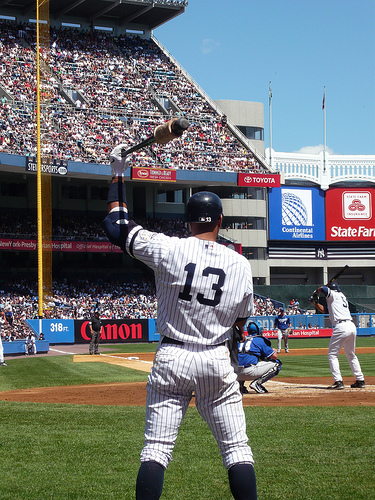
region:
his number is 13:
[169, 247, 226, 312]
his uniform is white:
[146, 245, 241, 390]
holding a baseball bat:
[100, 112, 187, 210]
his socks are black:
[114, 465, 253, 496]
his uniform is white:
[325, 288, 349, 359]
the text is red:
[61, 317, 147, 358]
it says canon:
[80, 319, 146, 344]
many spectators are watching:
[8, 272, 123, 358]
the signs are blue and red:
[270, 180, 368, 243]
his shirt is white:
[240, 329, 269, 363]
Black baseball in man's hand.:
[122, 119, 198, 159]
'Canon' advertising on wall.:
[74, 320, 148, 343]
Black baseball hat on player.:
[182, 193, 223, 224]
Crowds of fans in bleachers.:
[60, 55, 229, 167]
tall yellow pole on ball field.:
[33, 1, 49, 318]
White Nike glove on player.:
[107, 143, 135, 176]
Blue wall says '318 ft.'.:
[48, 322, 68, 333]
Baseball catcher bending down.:
[230, 321, 284, 393]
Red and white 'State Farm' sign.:
[324, 187, 373, 239]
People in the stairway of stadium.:
[73, 96, 86, 107]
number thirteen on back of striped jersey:
[177, 257, 227, 314]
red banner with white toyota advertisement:
[235, 170, 283, 190]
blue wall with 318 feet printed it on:
[47, 320, 73, 336]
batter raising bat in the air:
[101, 117, 278, 498]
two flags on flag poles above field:
[257, 66, 335, 179]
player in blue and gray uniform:
[272, 303, 300, 354]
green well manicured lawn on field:
[21, 405, 101, 483]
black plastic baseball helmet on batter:
[184, 191, 228, 230]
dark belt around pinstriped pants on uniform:
[142, 328, 242, 358]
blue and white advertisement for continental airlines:
[273, 185, 326, 242]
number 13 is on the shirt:
[178, 260, 230, 305]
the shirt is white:
[132, 230, 248, 336]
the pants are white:
[149, 350, 252, 451]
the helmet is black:
[186, 184, 222, 221]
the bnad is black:
[103, 183, 137, 208]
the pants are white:
[329, 329, 368, 375]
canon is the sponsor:
[80, 320, 145, 342]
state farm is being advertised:
[324, 193, 372, 238]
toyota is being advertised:
[242, 171, 279, 183]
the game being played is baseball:
[5, 176, 373, 498]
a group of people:
[10, 37, 241, 186]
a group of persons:
[6, 37, 269, 211]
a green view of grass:
[17, 398, 279, 494]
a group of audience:
[15, 20, 305, 209]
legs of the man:
[140, 384, 313, 438]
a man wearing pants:
[113, 337, 369, 483]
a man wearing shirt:
[157, 233, 335, 423]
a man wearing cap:
[175, 188, 255, 249]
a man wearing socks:
[122, 433, 262, 499]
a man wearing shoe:
[296, 375, 372, 393]